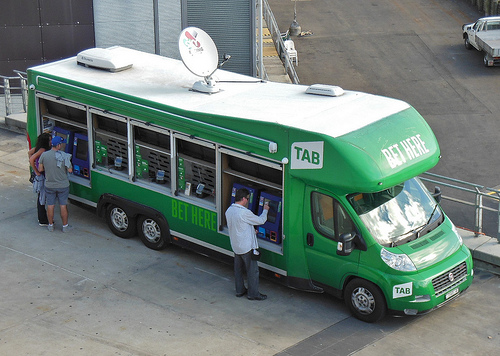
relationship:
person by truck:
[221, 187, 271, 302] [22, 41, 478, 320]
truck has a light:
[22, 41, 478, 320] [380, 249, 417, 277]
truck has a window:
[22, 41, 478, 320] [306, 189, 364, 255]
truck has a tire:
[22, 41, 478, 320] [341, 275, 389, 325]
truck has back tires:
[22, 41, 478, 320] [101, 204, 167, 251]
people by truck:
[29, 129, 76, 234] [22, 41, 478, 320]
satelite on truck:
[170, 23, 235, 95] [22, 41, 478, 320]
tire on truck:
[341, 275, 389, 325] [22, 41, 478, 320]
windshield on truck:
[349, 180, 443, 247] [22, 41, 478, 320]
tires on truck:
[101, 204, 167, 251] [22, 41, 478, 320]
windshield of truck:
[349, 180, 443, 247] [22, 41, 478, 320]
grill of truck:
[426, 261, 470, 292] [22, 41, 478, 320]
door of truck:
[301, 186, 368, 291] [22, 41, 478, 320]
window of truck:
[306, 189, 364, 255] [22, 41, 478, 320]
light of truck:
[380, 249, 417, 277] [22, 41, 478, 320]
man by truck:
[221, 187, 271, 302] [22, 41, 478, 320]